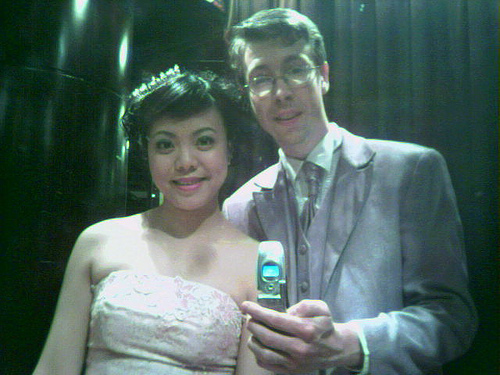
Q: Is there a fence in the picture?
A: No, there are no fences.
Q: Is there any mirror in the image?
A: Yes, there is a mirror.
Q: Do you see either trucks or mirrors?
A: Yes, there is a mirror.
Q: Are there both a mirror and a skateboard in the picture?
A: No, there is a mirror but no skateboards.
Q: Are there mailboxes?
A: No, there are no mailboxes.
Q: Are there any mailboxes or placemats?
A: No, there are no mailboxes or placemats.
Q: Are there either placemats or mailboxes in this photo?
A: No, there are no mailboxes or placemats.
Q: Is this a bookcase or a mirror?
A: This is a mirror.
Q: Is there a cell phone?
A: Yes, there is a cell phone.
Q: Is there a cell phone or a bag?
A: Yes, there is a cell phone.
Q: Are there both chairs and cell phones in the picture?
A: No, there is a cell phone but no chairs.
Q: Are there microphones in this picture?
A: No, there are no microphones.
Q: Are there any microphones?
A: No, there are no microphones.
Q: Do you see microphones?
A: No, there are no microphones.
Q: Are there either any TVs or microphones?
A: No, there are no microphones or tvs.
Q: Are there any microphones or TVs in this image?
A: No, there are no microphones or tvs.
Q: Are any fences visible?
A: No, there are no fences.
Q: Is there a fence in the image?
A: No, there are no fences.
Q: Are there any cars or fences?
A: No, there are no fences or cars.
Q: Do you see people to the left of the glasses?
A: Yes, there are people to the left of the glasses.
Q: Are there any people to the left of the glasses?
A: Yes, there are people to the left of the glasses.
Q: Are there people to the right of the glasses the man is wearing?
A: No, the people are to the left of the glasses.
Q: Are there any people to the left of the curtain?
A: Yes, there are people to the left of the curtain.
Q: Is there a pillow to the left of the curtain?
A: No, there are people to the left of the curtain.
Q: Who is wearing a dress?
A: The people are wearing a dress.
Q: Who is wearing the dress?
A: The people are wearing a dress.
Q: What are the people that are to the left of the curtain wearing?
A: The people are wearing a dress.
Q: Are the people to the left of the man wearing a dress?
A: Yes, the people are wearing a dress.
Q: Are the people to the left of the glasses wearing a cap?
A: No, the people are wearing a dress.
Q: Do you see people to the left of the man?
A: Yes, there are people to the left of the man.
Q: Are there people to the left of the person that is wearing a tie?
A: Yes, there are people to the left of the man.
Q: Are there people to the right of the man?
A: No, the people are to the left of the man.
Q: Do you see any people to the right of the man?
A: No, the people are to the left of the man.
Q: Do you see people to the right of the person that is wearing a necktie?
A: No, the people are to the left of the man.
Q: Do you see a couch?
A: No, there are no couches.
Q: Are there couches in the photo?
A: No, there are no couches.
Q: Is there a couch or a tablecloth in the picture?
A: No, there are no couches or tablecloths.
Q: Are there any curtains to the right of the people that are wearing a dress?
A: Yes, there is a curtain to the right of the people.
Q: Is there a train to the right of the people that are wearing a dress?
A: No, there is a curtain to the right of the people.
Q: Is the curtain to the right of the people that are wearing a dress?
A: Yes, the curtain is to the right of the people.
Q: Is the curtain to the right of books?
A: No, the curtain is to the right of the people.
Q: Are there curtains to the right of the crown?
A: Yes, there is a curtain to the right of the crown.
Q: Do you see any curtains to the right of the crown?
A: Yes, there is a curtain to the right of the crown.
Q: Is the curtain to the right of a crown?
A: Yes, the curtain is to the right of a crown.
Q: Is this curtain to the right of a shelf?
A: No, the curtain is to the right of a crown.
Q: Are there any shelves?
A: No, there are no shelves.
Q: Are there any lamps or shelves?
A: No, there are no shelves or lamps.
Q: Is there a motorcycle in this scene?
A: No, there are no motorcycles.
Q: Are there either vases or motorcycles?
A: No, there are no motorcycles or vases.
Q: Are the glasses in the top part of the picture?
A: Yes, the glasses are in the top of the image.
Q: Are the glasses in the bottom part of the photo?
A: No, the glasses are in the top of the image.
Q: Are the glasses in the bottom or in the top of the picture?
A: The glasses are in the top of the image.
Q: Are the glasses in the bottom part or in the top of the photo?
A: The glasses are in the top of the image.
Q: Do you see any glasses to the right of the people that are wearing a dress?
A: Yes, there are glasses to the right of the people.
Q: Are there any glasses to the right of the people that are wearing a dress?
A: Yes, there are glasses to the right of the people.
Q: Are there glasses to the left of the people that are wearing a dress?
A: No, the glasses are to the right of the people.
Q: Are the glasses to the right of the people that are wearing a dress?
A: Yes, the glasses are to the right of the people.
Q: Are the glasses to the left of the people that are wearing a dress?
A: No, the glasses are to the right of the people.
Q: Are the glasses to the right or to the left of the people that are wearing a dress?
A: The glasses are to the right of the people.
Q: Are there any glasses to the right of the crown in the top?
A: Yes, there are glasses to the right of the crown.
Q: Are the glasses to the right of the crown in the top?
A: Yes, the glasses are to the right of the crown.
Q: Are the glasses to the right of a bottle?
A: No, the glasses are to the right of the crown.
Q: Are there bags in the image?
A: No, there are no bags.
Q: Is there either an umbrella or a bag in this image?
A: No, there are no bags or umbrellas.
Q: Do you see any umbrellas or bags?
A: No, there are no bags or umbrellas.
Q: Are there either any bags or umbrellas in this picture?
A: No, there are no bags or umbrellas.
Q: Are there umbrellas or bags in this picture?
A: No, there are no bags or umbrellas.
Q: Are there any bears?
A: No, there are no bears.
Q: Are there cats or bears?
A: No, there are no bears or cats.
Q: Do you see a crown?
A: Yes, there is a crown.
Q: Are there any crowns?
A: Yes, there is a crown.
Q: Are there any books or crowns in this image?
A: Yes, there is a crown.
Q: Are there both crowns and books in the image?
A: No, there is a crown but no books.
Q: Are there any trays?
A: No, there are no trays.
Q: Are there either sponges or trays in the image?
A: No, there are no trays or sponges.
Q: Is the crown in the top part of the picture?
A: Yes, the crown is in the top of the image.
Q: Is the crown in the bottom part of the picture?
A: No, the crown is in the top of the image.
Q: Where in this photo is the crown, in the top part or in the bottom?
A: The crown is in the top of the image.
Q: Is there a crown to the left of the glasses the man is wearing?
A: Yes, there is a crown to the left of the glasses.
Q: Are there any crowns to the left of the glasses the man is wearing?
A: Yes, there is a crown to the left of the glasses.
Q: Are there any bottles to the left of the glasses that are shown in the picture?
A: No, there is a crown to the left of the glasses.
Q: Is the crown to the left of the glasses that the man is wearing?
A: Yes, the crown is to the left of the glasses.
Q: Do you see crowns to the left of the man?
A: Yes, there is a crown to the left of the man.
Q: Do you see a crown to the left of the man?
A: Yes, there is a crown to the left of the man.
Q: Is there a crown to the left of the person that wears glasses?
A: Yes, there is a crown to the left of the man.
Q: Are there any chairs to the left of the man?
A: No, there is a crown to the left of the man.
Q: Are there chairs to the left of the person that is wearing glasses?
A: No, there is a crown to the left of the man.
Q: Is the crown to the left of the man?
A: Yes, the crown is to the left of the man.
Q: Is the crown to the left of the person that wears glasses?
A: Yes, the crown is to the left of the man.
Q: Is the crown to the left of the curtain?
A: Yes, the crown is to the left of the curtain.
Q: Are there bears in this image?
A: No, there are no bears.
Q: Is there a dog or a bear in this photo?
A: No, there are no bears or dogs.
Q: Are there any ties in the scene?
A: Yes, there is a tie.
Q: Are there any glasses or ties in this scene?
A: Yes, there is a tie.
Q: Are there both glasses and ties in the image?
A: Yes, there are both a tie and glasses.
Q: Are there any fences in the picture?
A: No, there are no fences.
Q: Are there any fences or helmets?
A: No, there are no fences or helmets.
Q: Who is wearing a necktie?
A: The man is wearing a necktie.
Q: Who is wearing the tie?
A: The man is wearing a necktie.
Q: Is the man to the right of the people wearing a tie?
A: Yes, the man is wearing a tie.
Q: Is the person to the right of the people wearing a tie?
A: Yes, the man is wearing a tie.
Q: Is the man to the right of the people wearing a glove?
A: No, the man is wearing a tie.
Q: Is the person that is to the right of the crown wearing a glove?
A: No, the man is wearing a tie.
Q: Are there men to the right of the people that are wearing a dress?
A: Yes, there is a man to the right of the people.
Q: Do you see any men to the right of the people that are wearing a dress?
A: Yes, there is a man to the right of the people.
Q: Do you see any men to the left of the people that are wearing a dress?
A: No, the man is to the right of the people.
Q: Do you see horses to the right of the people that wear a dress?
A: No, there is a man to the right of the people.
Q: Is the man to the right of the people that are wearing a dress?
A: Yes, the man is to the right of the people.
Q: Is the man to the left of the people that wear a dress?
A: No, the man is to the right of the people.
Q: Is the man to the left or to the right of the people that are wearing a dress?
A: The man is to the right of the people.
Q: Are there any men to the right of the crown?
A: Yes, there is a man to the right of the crown.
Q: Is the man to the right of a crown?
A: Yes, the man is to the right of a crown.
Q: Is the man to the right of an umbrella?
A: No, the man is to the right of a crown.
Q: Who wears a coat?
A: The man wears a coat.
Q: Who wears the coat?
A: The man wears a coat.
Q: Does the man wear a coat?
A: Yes, the man wears a coat.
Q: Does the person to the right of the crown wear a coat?
A: Yes, the man wears a coat.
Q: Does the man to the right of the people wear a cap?
A: No, the man wears a coat.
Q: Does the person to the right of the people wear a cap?
A: No, the man wears a coat.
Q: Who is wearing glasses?
A: The man is wearing glasses.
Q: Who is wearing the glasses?
A: The man is wearing glasses.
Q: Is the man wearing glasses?
A: Yes, the man is wearing glasses.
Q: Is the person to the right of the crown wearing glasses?
A: Yes, the man is wearing glasses.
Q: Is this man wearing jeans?
A: No, the man is wearing glasses.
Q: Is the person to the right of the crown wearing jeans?
A: No, the man is wearing glasses.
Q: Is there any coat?
A: Yes, there is a coat.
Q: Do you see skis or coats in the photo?
A: Yes, there is a coat.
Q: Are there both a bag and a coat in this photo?
A: No, there is a coat but no bags.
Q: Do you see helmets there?
A: No, there are no helmets.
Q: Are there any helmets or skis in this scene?
A: No, there are no helmets or skis.